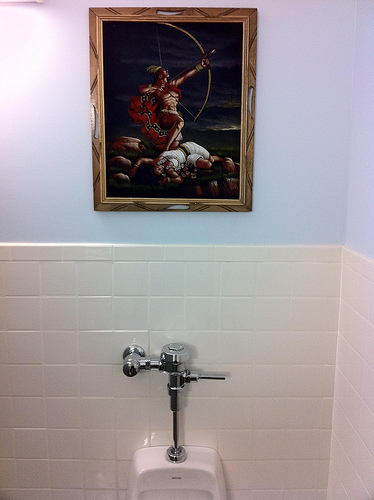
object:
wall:
[260, 16, 363, 229]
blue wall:
[4, 3, 92, 231]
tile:
[39, 261, 78, 296]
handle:
[181, 372, 225, 386]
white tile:
[217, 296, 253, 332]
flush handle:
[201, 373, 226, 382]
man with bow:
[129, 25, 217, 155]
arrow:
[170, 51, 216, 84]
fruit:
[193, 179, 233, 197]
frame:
[91, 8, 107, 213]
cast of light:
[5, 1, 52, 157]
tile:
[111, 261, 146, 299]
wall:
[4, 247, 116, 495]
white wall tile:
[6, 261, 40, 301]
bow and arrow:
[153, 25, 218, 117]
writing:
[170, 474, 184, 482]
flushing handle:
[184, 372, 199, 385]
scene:
[1, 1, 370, 498]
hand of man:
[197, 51, 218, 69]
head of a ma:
[149, 64, 171, 87]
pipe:
[120, 347, 145, 376]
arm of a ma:
[173, 60, 201, 83]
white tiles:
[47, 428, 82, 460]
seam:
[324, 0, 342, 497]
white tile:
[76, 292, 115, 334]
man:
[134, 63, 211, 157]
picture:
[87, 7, 253, 210]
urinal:
[116, 345, 230, 498]